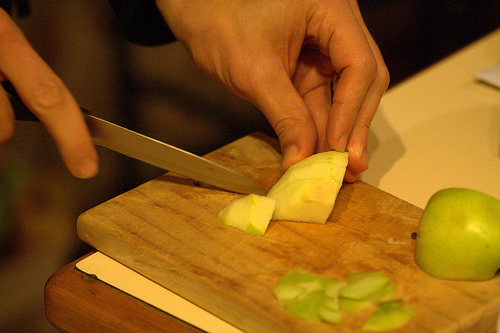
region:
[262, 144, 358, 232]
sliced piece of apple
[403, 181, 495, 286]
half of green apple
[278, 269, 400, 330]
pieces of apple on cutting board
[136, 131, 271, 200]
metal of knife blade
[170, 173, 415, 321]
cutting board on table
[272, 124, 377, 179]
finger tips on apple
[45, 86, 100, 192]
index finger on knife handle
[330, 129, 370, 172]
nails on finger tips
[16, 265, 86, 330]
corner of wood table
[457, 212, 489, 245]
light reflection on apple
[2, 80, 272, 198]
silver knife with black handle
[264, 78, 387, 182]
fingers holding food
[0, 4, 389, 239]
person cutting fruit with knife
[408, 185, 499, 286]
half of green fruit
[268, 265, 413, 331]
shavings of peal on cutting board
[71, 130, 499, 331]
small brown cutting board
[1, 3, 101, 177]
fingers holding knife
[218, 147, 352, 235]
small slices of the fruit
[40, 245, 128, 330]
corner of the counter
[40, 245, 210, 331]
wooden edge of counter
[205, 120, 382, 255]
a sliced up apple.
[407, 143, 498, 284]
a green apple on a cutting board.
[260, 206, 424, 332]
apple slices on a cutting board.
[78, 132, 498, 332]
a wooden cutting board.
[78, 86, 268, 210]
a knife on a cutting board.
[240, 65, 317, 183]
a thumb on an apple.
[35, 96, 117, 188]
a pointer finger on a knife.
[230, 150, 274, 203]
the tip of a knife..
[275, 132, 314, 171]
a finger nail on a thumb.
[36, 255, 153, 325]
the corner of a counter.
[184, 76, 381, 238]
person cutting an apple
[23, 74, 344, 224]
hand holding knife cutting apple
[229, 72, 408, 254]
fingers holding apple on cutting board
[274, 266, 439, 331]
green peel of apple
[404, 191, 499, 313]
part of apple on cutting board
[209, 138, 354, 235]
slices of apple on cutting board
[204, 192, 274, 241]
piece of peeled apple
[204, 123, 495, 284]
cutting board on countertop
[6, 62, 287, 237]
black handle on knife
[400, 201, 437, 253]
brown stem on apple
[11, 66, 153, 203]
finger gripping cutting knife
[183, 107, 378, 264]
knife cutting into an apple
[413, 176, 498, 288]
green sliced apple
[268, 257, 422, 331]
apple slicings that have been knifed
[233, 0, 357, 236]
hand holding apple while cutting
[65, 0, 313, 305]
knife slicing into apple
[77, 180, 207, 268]
corner of wooden cutting board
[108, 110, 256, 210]
stainless steel knife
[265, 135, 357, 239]
apple being cut in half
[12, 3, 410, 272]
hand cutting apple in half with knife